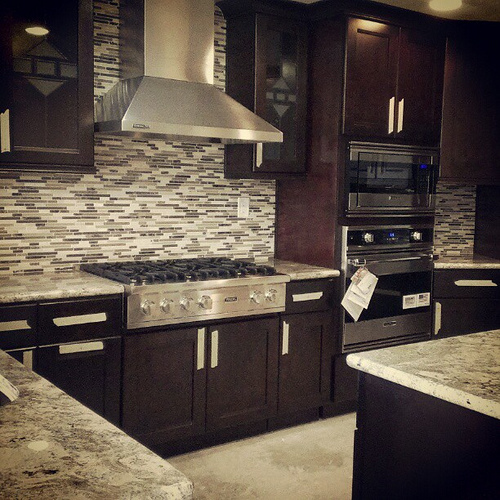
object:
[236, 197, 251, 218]
electrical pad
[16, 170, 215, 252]
wall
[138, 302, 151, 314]
control knobs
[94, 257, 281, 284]
burners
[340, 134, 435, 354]
oven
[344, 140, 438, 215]
microwave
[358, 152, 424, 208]
glass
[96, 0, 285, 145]
overhead vent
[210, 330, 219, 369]
tape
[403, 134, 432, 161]
wall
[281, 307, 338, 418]
cabinet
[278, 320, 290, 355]
strip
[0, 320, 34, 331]
tape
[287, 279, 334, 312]
brown drawer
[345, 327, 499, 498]
kitchen island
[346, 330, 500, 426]
marble countertop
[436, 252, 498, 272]
marble countertop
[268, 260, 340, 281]
marble countertop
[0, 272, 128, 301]
marble countertop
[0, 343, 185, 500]
marble countertop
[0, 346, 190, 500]
counter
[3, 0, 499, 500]
kitchen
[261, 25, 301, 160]
design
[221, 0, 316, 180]
cabinet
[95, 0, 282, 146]
vent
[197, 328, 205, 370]
strip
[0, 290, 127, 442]
cabinet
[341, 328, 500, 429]
counter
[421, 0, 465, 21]
light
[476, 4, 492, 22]
ceiling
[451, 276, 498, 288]
tape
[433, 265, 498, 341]
cabinet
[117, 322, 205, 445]
cabinet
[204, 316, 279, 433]
cabinet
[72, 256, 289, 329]
oven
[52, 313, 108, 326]
tape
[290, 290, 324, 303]
tape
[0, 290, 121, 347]
drawer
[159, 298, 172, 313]
knobs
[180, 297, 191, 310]
knobs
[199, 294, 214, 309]
knobs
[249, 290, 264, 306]
knobs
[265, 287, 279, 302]
knobs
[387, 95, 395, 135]
tape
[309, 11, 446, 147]
cabinet